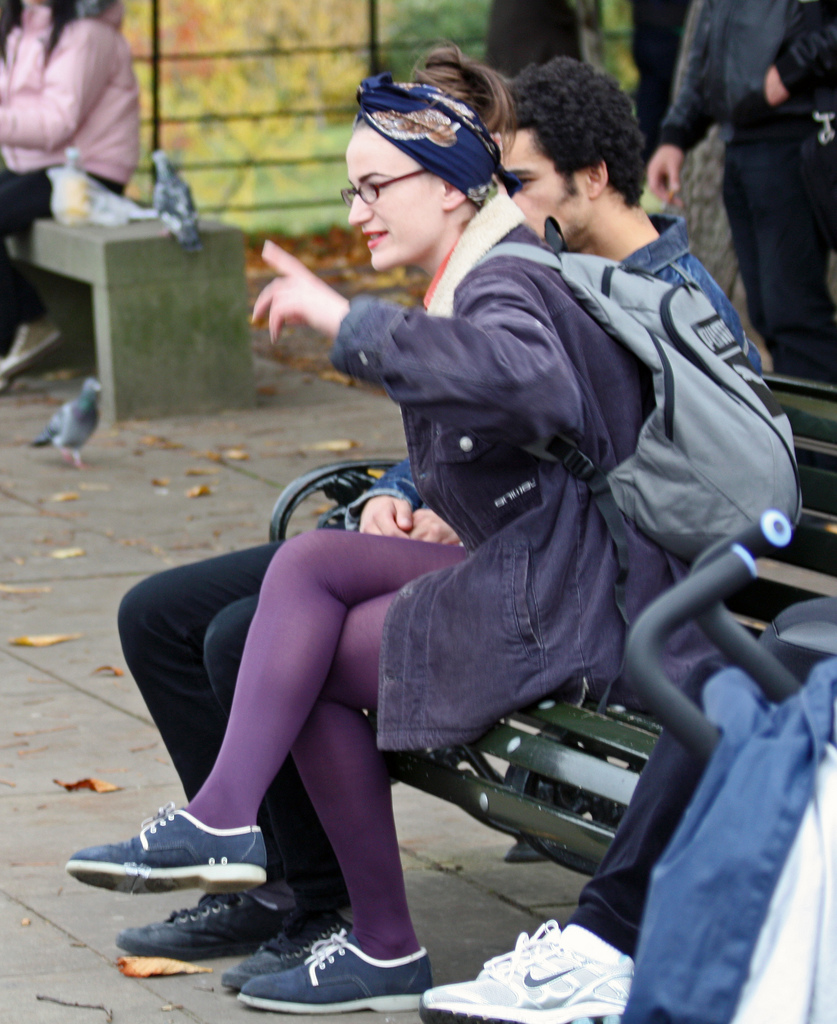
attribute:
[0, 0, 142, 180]
coat — pink, fluffy